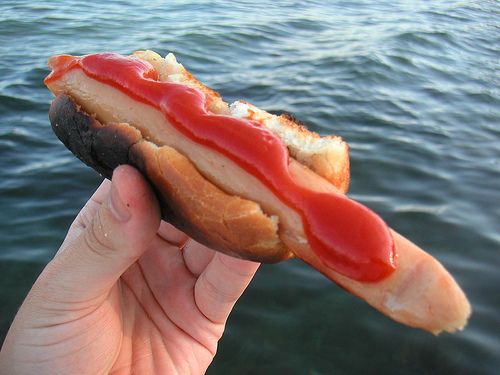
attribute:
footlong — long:
[42, 49, 473, 337]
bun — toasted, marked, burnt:
[48, 47, 351, 265]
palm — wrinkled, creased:
[112, 257, 196, 375]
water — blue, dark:
[0, 0, 498, 370]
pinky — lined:
[193, 250, 266, 328]